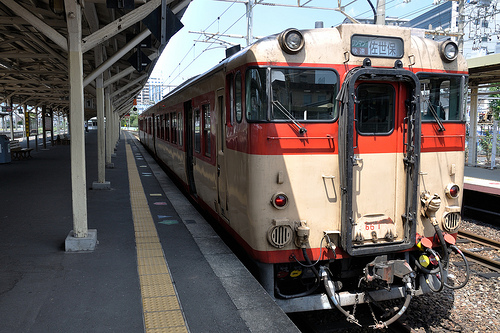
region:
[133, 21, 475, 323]
The train in the station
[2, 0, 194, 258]
The cover over the train station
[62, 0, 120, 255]
The supports of the patio cover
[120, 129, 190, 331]
The yellow line on the station platform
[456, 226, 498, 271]
The empty tracks next to the train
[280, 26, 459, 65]
The lights at the top of the train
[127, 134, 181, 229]
The multiple colored symbols on the platform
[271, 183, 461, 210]
The red lights on the train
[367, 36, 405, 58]
the Asian writing on the train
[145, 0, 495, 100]
The wires hanging over the train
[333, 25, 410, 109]
Asian writing on train.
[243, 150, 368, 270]
Train is mostly peach.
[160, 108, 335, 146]
Red strip around side of train.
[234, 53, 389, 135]
Large window on rear of train.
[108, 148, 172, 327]
Yellow stripe on platform.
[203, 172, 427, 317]
Train on tracks near platform.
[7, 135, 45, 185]
Bench on concrete in platform area.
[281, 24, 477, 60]
Lights on back of train.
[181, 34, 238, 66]
Sky is bright and blue.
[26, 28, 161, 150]
Platform area has large overhang.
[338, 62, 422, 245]
the door of a train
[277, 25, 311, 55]
a headlight on the train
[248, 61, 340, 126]
a windshield on the train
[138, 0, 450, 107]
a blue sky overhead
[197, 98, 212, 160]
a passenger window on the train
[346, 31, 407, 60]
writing on the train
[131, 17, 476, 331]
a train on the tracks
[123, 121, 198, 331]
a yellow line on the ground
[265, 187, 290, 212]
a red light on the train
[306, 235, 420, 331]
a black wire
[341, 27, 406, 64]
Writing is in Chinese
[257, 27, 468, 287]
Bus is beige and red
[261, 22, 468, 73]
Top of bus is dirty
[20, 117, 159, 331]
Platform is empty of passenger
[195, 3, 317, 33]
Sky appears to be clear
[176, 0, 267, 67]
Electrical wires above bus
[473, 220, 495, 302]
Rocks in the tracks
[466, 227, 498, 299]
Tracks are old and rusty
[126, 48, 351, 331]
Bus is parked next to curb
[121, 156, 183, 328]
Yellow, bumpy strip on sidewalk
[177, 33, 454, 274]
picture taken outdoors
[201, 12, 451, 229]
picture taken during the day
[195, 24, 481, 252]
a train is at the station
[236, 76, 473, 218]
the train is red and tan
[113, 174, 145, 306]
a yellow line is on the ground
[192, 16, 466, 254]
the sun is shining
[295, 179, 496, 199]
the lights on the train are red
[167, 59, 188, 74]
the sky is blue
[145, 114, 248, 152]
the train has lots of windows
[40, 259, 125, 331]
the ground is dark gray